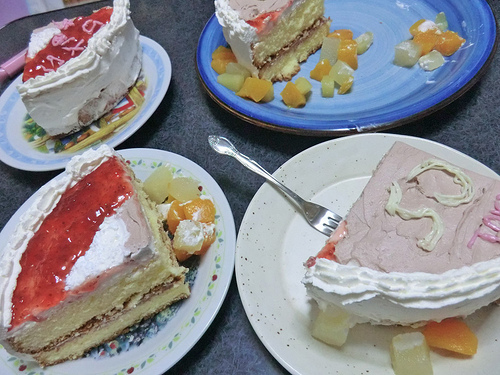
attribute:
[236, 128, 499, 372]
plate — white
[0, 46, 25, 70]
object — pink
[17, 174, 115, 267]
sauce — red, fruit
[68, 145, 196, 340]
plate — round, blue, small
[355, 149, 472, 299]
icing — pink, white, writing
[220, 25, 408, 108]
plate — blue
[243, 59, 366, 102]
peach — diced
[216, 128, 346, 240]
fork — silver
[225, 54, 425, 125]
fruit — chunks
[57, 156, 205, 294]
cake — large, layers, strawberry, filled, served, plastic